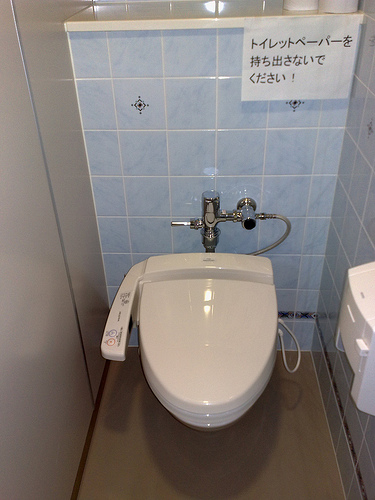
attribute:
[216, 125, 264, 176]
tile — blue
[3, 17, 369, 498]
toilet stall — single, empty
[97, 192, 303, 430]
toilet — white , down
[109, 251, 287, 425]
toilet — white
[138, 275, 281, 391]
seat — white, clean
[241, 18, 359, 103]
sign — white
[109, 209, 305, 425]
toilet. — white 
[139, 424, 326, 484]
floor — bathroom , section 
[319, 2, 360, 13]
toilet paper — rolled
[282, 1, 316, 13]
toilet paper — rolled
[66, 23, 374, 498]
wall — blue and white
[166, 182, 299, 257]
chrome — shiny , clean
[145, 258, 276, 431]
toilet seat — toilet 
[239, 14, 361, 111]
symbols — written, Japanese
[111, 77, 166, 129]
flower — symbol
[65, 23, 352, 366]
wall — blue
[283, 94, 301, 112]
accent — black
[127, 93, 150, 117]
accent — black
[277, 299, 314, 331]
accent — black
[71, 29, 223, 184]
wall — multi-colored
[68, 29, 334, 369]
tile wall — blue and white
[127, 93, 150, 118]
design — black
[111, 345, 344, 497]
floor — tan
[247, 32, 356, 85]
letters — black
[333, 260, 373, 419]
paper dispenser — white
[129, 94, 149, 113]
art — multi-colored